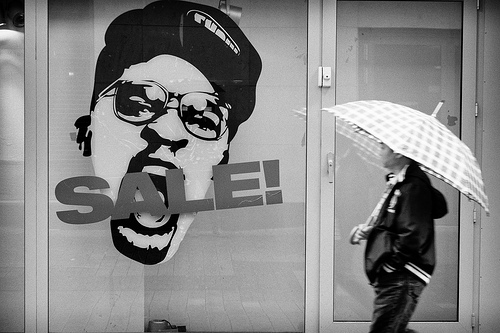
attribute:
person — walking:
[350, 141, 450, 333]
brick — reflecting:
[51, 235, 305, 333]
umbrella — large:
[321, 99, 490, 245]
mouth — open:
[132, 159, 175, 228]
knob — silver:
[326, 152, 335, 184]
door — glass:
[324, 1, 475, 333]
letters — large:
[57, 161, 264, 226]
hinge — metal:
[475, 104, 480, 117]